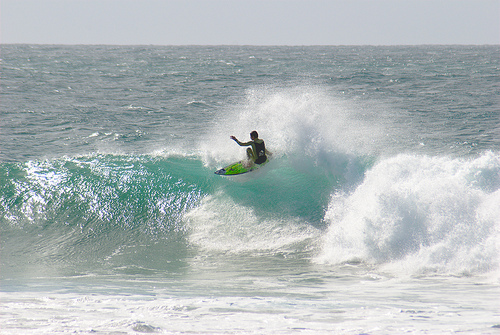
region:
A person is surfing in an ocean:
[157, 99, 325, 221]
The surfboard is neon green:
[201, 145, 266, 193]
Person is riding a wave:
[203, 108, 298, 206]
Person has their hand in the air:
[215, 118, 259, 154]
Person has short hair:
[242, 125, 263, 145]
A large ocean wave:
[216, 107, 472, 260]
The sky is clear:
[3, 3, 498, 45]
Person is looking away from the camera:
[239, 119, 271, 152]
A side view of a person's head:
[246, 126, 263, 146]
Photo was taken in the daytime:
[3, 3, 498, 320]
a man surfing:
[150, 66, 496, 252]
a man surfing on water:
[147, 15, 460, 320]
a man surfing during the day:
[169, 66, 376, 259]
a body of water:
[52, 80, 225, 317]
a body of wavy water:
[59, 88, 279, 303]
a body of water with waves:
[50, 77, 189, 334]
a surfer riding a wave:
[187, 41, 347, 309]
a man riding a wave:
[89, 50, 449, 256]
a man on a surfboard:
[123, 80, 411, 244]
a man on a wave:
[79, 52, 424, 319]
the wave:
[361, 166, 464, 246]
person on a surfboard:
[222, 124, 288, 176]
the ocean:
[98, 46, 215, 117]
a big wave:
[111, 169, 305, 255]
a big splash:
[267, 95, 349, 151]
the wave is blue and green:
[85, 158, 170, 207]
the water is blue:
[363, 63, 493, 145]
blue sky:
[155, 11, 300, 38]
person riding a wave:
[207, 130, 308, 191]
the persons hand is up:
[226, 127, 288, 174]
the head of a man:
[246, 127, 263, 142]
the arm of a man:
[234, 136, 251, 148]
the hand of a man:
[225, 128, 237, 143]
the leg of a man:
[242, 144, 259, 167]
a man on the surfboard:
[226, 122, 274, 170]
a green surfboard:
[209, 145, 291, 182]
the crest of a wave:
[0, 145, 496, 186]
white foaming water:
[315, 147, 495, 277]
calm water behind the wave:
[1, 41, 499, 93]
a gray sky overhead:
[1, 0, 499, 48]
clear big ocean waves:
[308, 90, 492, 332]